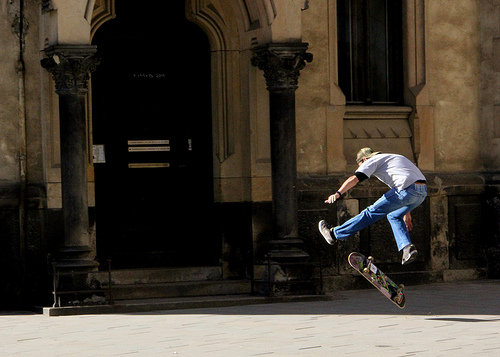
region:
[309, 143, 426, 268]
person in the air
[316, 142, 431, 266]
person doing a skateboard trick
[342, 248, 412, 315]
skateboard in the air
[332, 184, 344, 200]
black band on man's left wrist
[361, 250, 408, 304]
yellow wheels on a skateboard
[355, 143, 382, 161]
backwards hat on a man's head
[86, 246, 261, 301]
steps in front of a building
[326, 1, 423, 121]
window on a building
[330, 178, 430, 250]
man's pair of blue jeans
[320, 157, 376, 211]
man's outstretched left hand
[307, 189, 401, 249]
leg of a person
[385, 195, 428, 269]
leg of a person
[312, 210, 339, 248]
foot of a person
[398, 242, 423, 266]
foot of a person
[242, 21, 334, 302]
pillar on a building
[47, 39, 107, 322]
pillar on a building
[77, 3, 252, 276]
large doorway on a building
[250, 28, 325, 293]
large black support pillar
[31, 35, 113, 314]
large black support pillar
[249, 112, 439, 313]
a man doing a skateboard stunt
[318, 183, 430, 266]
the legs of a man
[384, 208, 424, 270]
the leg of a man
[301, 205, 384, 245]
the leg of a man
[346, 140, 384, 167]
the head of a man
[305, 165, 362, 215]
the arm of a man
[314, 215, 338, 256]
the foot of a man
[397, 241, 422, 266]
the foot of a man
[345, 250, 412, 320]
the backside of a stakeboard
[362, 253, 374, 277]
the wheels on a skateboard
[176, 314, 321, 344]
a smooth grey sidewalk.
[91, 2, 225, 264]
a big front black door.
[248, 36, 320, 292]
a thick black pole.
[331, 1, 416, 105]
a dark front window.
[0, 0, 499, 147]
a big huge brick beige and black building.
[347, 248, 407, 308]
the bottom of a skate board.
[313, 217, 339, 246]
a man is wearing black sneakers.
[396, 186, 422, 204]
a man is wearing blue jeans.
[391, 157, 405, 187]
a man is wearing a grey shirt.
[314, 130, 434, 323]
a man is jumping up on the skate board.